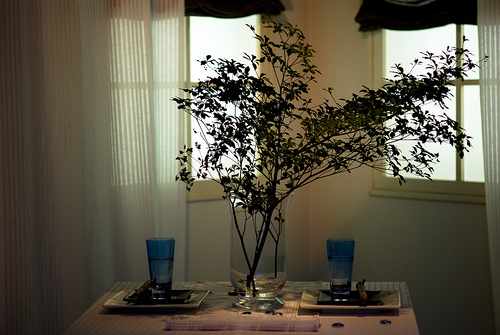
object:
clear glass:
[146, 237, 175, 300]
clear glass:
[326, 238, 356, 302]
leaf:
[380, 319, 392, 325]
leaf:
[331, 322, 344, 327]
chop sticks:
[356, 279, 369, 305]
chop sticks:
[130, 280, 152, 306]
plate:
[299, 288, 401, 312]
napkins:
[163, 309, 321, 332]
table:
[59, 280, 419, 334]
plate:
[101, 289, 211, 308]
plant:
[167, 0, 490, 298]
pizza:
[117, 8, 499, 198]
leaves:
[348, 83, 405, 112]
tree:
[169, 0, 489, 297]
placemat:
[163, 280, 323, 332]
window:
[105, 13, 261, 187]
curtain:
[0, 0, 187, 335]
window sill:
[368, 176, 485, 205]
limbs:
[252, 43, 295, 101]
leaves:
[322, 94, 373, 126]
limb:
[315, 158, 336, 179]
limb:
[344, 128, 364, 150]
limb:
[357, 156, 391, 176]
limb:
[387, 134, 410, 146]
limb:
[262, 157, 280, 188]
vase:
[325, 237, 356, 302]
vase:
[224, 188, 294, 312]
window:
[380, 21, 484, 183]